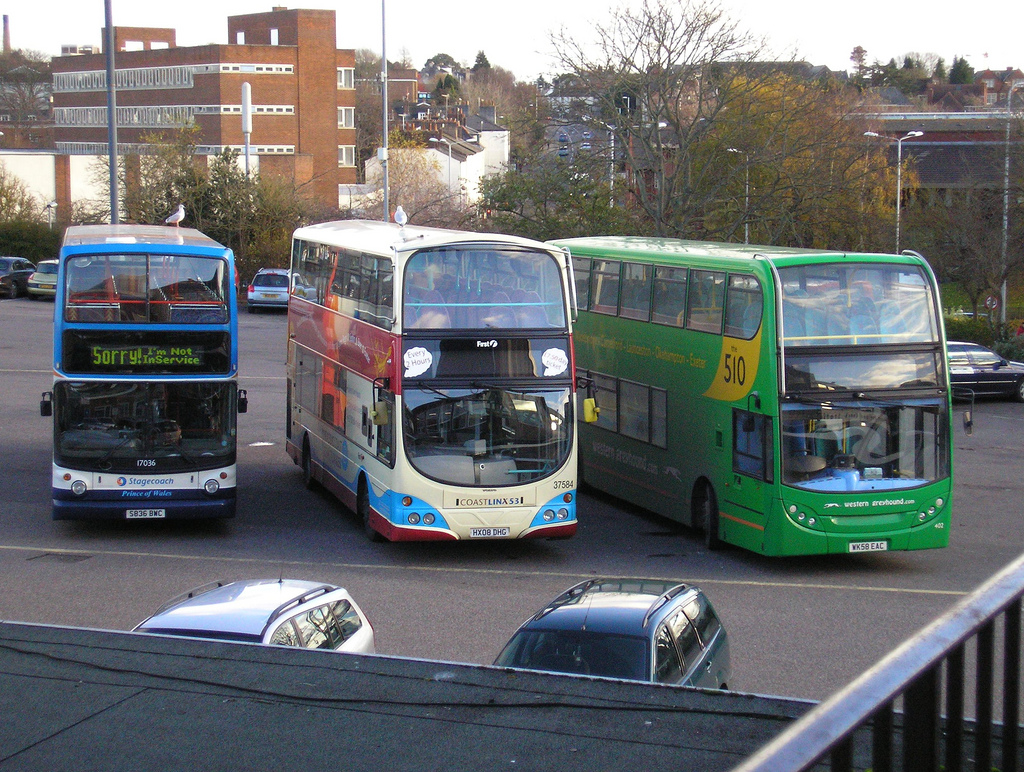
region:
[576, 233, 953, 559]
green double decker tour bus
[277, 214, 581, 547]
red white and blue double decker tour bus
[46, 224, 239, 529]
blue double decker tour bus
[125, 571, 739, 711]
white and blue cars parked in a lot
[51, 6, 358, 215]
multi-story brick building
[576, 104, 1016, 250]
street lights seen behind trees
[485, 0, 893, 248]
bank of trees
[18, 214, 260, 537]
blue double deck passenger bus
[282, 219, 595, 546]
colorful double deck passenger bus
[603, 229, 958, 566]
green double deck passenger bus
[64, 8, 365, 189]
large brown and white building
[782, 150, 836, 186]
green and brown leaves in tree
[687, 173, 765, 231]
green and brown leaves in tree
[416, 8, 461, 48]
white clouds in blue sky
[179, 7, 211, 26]
white clouds in blue sky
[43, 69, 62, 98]
a window on a building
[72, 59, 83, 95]
a window on a building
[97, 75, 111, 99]
a window on a building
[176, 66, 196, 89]
a window on a building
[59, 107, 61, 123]
a window on a building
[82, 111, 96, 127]
a window on a building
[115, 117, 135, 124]
a window on a building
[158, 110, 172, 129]
a window on a building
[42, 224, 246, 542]
Blue double decker bus with "Sorry" message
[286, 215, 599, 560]
Multi color double decker bus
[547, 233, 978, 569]
Large green double decker bus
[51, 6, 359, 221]
A brownstone building in the distance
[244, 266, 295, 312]
A grey sedan that is parked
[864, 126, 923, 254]
A streetlight in the parking lot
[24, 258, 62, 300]
An old cream colored sedan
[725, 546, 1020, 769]
A metal railing on the roof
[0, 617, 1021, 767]
The roof of a building in a parking lot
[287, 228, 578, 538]
red,white & blue double decker bus parked in a lot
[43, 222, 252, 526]
blue & white double decker bus parked in a lot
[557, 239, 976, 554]
green double decker bus parked in a lot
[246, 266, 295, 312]
silver vehicle parked in a lot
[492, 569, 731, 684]
dark green vehicle parked in a lot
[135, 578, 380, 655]
silver vehicle parked in a lot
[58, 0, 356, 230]
tall brick building erected in background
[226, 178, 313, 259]
tall green bush growing in front of building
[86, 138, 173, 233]
tall green bush growing in front of building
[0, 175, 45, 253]
tall green bush growing in front of building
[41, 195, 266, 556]
blue and black bus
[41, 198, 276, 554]
blue and black bus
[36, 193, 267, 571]
blue and black bus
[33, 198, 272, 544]
blue and black bus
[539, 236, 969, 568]
The bus on the right is green in color.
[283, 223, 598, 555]
The bus in the middle is red, white and blue.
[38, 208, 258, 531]
The bus on the left is blue in color.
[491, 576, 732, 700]
The car parked on the right is blue in color.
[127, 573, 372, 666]
The car parked on the left is white in color.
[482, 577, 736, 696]
The blue car is parked on the pavement.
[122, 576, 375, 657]
The white car is parked on the pavement.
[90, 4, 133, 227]
The pole on the left is made from metal.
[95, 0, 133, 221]
The pole on the left is gray in color.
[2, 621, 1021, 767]
The roof is black in color.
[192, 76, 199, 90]
a window on the building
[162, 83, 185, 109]
a window on the building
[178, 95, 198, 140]
a window on the building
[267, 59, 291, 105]
a window on the building